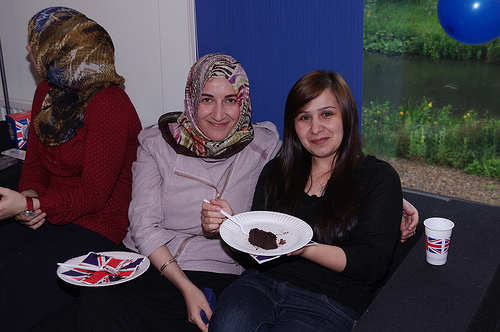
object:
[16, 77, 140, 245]
red blouse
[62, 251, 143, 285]
crumbs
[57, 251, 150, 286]
plate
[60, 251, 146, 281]
flag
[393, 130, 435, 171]
ground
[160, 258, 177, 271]
band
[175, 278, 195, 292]
wrist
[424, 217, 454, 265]
cup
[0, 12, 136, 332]
person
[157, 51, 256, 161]
material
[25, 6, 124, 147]
material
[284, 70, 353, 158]
head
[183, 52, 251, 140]
head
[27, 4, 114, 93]
head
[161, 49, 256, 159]
wrap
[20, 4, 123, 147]
wrap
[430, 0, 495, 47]
balloon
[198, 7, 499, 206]
window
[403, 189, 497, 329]
sofa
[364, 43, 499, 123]
waterway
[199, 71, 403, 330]
person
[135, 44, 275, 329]
person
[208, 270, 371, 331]
jeans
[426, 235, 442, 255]
british flag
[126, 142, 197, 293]
arm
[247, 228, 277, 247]
cake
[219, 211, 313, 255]
plate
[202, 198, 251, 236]
fork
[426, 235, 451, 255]
design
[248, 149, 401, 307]
shirt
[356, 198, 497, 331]
ledge